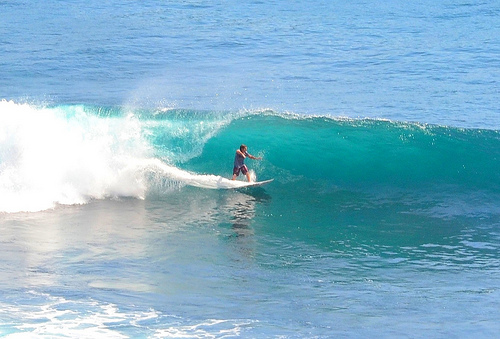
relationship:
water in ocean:
[22, 79, 132, 212] [19, 14, 479, 328]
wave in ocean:
[4, 96, 498, 216] [5, 42, 471, 326]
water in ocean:
[22, 79, 132, 212] [6, 22, 445, 336]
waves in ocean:
[308, 115, 444, 165] [41, 39, 422, 329]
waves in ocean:
[308, 115, 444, 165] [81, 103, 467, 312]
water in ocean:
[22, 79, 132, 212] [23, 36, 445, 323]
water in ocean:
[22, 79, 132, 212] [41, 39, 422, 329]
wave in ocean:
[4, 96, 498, 216] [19, 14, 479, 328]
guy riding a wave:
[232, 144, 261, 183] [62, 61, 457, 264]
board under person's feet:
[183, 176, 274, 190] [221, 161, 274, 183]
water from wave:
[22, 79, 132, 212] [14, 45, 461, 264]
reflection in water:
[219, 187, 253, 262] [38, 92, 481, 318]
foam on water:
[23, 274, 151, 331] [10, 25, 442, 336]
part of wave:
[328, 103, 374, 143] [209, 73, 489, 233]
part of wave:
[149, 112, 246, 175] [82, 62, 389, 295]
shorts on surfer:
[233, 162, 247, 174] [231, 141, 261, 181]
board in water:
[183, 176, 274, 190] [2, 0, 498, 336]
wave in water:
[4, 96, 498, 216] [2, 0, 498, 336]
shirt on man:
[236, 151, 248, 166] [229, 144, 259, 178]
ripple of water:
[214, 38, 248, 48] [2, 0, 498, 336]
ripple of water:
[183, 42, 222, 51] [2, 0, 498, 336]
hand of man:
[258, 155, 265, 159] [230, 142, 261, 180]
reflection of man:
[219, 187, 276, 234] [230, 143, 262, 182]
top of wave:
[261, 109, 497, 139] [4, 96, 498, 216]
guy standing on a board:
[232, 144, 261, 183] [218, 178, 273, 188]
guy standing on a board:
[232, 144, 261, 183] [210, 177, 272, 188]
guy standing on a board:
[232, 144, 261, 183] [183, 176, 274, 190]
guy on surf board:
[234, 148, 257, 180] [214, 175, 291, 192]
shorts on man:
[234, 164, 249, 175] [227, 140, 256, 182]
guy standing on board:
[232, 144, 261, 183] [200, 179, 275, 195]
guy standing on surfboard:
[232, 144, 261, 183] [186, 171, 279, 196]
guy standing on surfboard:
[232, 144, 261, 183] [175, 172, 273, 195]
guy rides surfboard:
[232, 144, 261, 183] [221, 177, 275, 193]